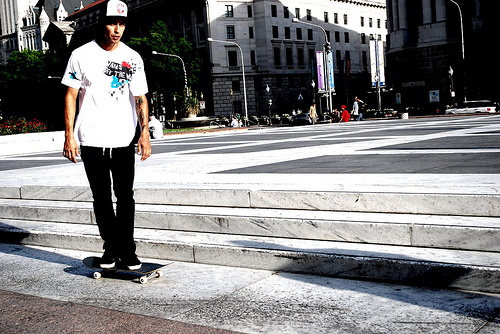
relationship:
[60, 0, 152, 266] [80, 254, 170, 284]
man standing on top of skateboard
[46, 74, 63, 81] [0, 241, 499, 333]
lamp post lining sidewalk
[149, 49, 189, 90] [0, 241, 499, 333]
lamp post lining sidewalk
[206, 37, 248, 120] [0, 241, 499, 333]
lamp post lining sidewalk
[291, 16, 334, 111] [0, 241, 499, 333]
lamp post lining sidewalk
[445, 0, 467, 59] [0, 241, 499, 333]
lamp post lining sidewalk